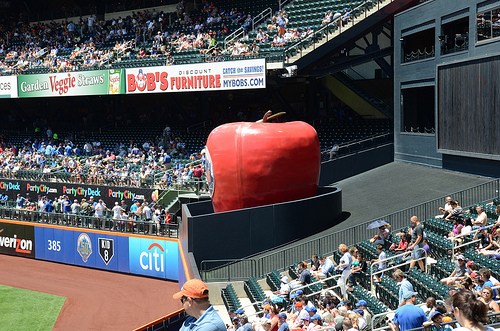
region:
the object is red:
[194, 121, 331, 197]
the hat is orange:
[163, 277, 216, 304]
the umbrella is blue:
[356, 210, 395, 253]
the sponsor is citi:
[129, 240, 177, 290]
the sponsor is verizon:
[4, 223, 35, 259]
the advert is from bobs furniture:
[126, 68, 266, 92]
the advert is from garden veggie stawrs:
[21, 68, 118, 98]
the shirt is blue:
[395, 304, 435, 327]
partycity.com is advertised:
[105, 185, 150, 205]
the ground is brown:
[52, 266, 157, 320]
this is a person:
[168, 276, 225, 326]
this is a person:
[271, 312, 286, 329]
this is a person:
[383, 267, 419, 298]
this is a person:
[448, 284, 495, 329]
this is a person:
[365, 233, 395, 278]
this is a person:
[320, 227, 366, 295]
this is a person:
[402, 203, 438, 270]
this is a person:
[437, 192, 467, 232]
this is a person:
[463, 190, 494, 248]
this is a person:
[103, 190, 131, 230]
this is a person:
[381, 288, 432, 329]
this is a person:
[477, 280, 499, 309]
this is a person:
[365, 203, 390, 255]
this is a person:
[338, 242, 361, 289]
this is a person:
[93, 196, 108, 226]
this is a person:
[129, 198, 154, 224]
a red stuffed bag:
[193, 106, 330, 206]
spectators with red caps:
[258, 305, 340, 330]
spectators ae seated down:
[262, 312, 363, 329]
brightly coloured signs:
[11, 61, 261, 92]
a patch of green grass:
[2, 273, 79, 330]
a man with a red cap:
[172, 280, 227, 328]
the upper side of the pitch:
[0, 0, 380, 102]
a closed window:
[397, 85, 437, 135]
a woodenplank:
[438, 67, 499, 152]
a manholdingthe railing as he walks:
[408, 213, 430, 269]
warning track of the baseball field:
[1, 253, 191, 327]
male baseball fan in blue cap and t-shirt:
[395, 289, 418, 329]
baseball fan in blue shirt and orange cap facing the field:
[168, 276, 232, 329]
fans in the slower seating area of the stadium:
[223, 190, 494, 328]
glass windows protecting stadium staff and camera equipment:
[398, 0, 498, 141]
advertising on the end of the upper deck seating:
[0, 59, 290, 92]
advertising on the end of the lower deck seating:
[0, 212, 188, 286]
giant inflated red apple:
[199, 106, 326, 216]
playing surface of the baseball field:
[2, 279, 68, 328]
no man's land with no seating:
[180, 138, 499, 280]